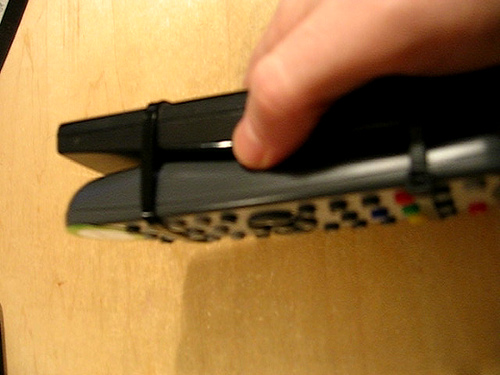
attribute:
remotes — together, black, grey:
[87, 123, 194, 226]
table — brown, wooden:
[126, 10, 157, 36]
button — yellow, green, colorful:
[383, 178, 434, 220]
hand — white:
[302, 4, 456, 57]